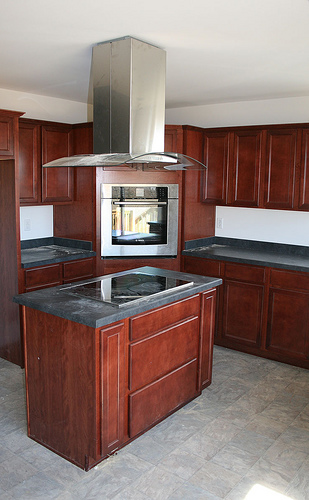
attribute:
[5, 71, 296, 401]
kitchen — metal, glass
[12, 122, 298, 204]
cabinets — dark red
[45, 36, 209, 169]
vent — large 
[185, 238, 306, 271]
counter top — black 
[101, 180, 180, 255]
oven — chrome-colored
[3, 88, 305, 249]
wall — white 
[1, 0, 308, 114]
ceiling — white 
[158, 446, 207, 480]
floor — tile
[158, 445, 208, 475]
tile — silver 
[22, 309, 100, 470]
wood — brown 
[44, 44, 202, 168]
hood — chrome 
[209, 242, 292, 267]
countertop — marble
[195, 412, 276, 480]
tile floor — light colored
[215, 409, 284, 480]
floor tiles — grey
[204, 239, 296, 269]
counter — grey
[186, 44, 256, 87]
ceiling — clear, white